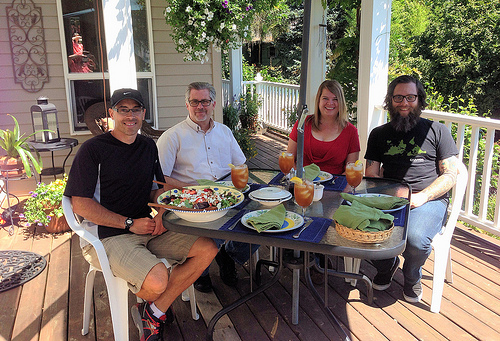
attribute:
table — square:
[139, 158, 446, 238]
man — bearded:
[364, 66, 439, 182]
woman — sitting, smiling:
[268, 22, 338, 165]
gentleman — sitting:
[169, 78, 256, 179]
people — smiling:
[32, 44, 493, 297]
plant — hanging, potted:
[179, 6, 240, 62]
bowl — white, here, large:
[155, 176, 256, 250]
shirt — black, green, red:
[362, 122, 470, 199]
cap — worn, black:
[94, 81, 168, 109]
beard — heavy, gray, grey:
[376, 106, 436, 144]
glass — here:
[285, 173, 314, 202]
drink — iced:
[231, 167, 260, 191]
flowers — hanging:
[167, 1, 238, 69]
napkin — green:
[341, 200, 380, 222]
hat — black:
[109, 82, 148, 96]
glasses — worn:
[384, 91, 444, 106]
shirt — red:
[292, 110, 381, 189]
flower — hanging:
[214, 16, 239, 42]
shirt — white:
[155, 118, 254, 183]